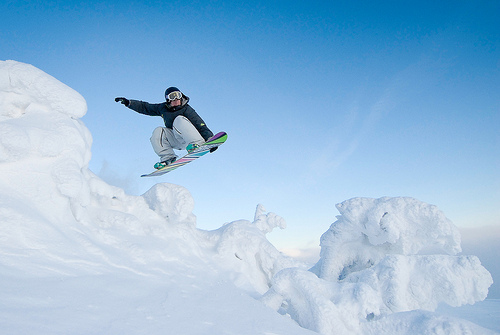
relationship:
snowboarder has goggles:
[115, 89, 229, 180] [165, 92, 183, 103]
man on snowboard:
[115, 87, 219, 170] [140, 132, 230, 179]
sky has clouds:
[1, 1, 499, 242] [313, 71, 417, 179]